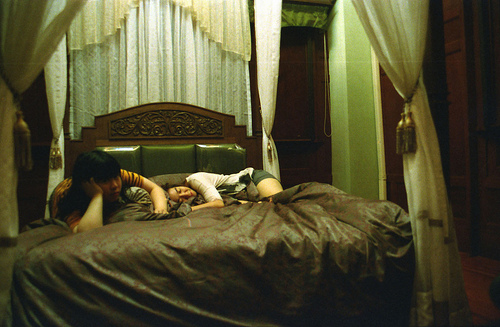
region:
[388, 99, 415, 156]
golden tassel on curtains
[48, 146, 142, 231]
woman with black hair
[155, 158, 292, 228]
woman laying on bed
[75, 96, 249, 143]
brown wooden bed headboard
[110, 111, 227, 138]
design on bed headboard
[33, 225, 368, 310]
brown bed comforter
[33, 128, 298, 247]
two women laying on bed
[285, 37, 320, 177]
large brown wooden door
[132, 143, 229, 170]
green cushions on bed headboard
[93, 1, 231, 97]
white curtains behind bed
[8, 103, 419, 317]
two people in a queen size bed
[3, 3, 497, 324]
a bed in a bedroom with people in it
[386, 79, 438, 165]
a tassel of a bedroom curtain to keep out mosquitoes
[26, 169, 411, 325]
a brown bed spread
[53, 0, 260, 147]
a white curtain covering window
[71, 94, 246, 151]
a wooden head board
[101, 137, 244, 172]
a group of pillows along head board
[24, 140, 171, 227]
a guy lying in bed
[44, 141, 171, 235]
a guy is laying with his head in his hand on a bed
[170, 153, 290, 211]
a woman is laying down with clothes on in bed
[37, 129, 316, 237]
people lying on a bed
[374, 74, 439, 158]
tassels on a bed curtain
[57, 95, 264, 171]
headboard of a bed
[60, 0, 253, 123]
curtains in a bedroom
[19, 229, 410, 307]
comforter on a bed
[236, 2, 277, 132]
wooden post of a bed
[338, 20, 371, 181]
green wall in a bedroom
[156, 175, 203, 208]
face of a sleeping woman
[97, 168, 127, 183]
eyes of an Asian woman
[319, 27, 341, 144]
rope to a shade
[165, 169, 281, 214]
The girl laying down.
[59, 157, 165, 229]
The girl leaning on her hand.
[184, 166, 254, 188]
The white shirt the girl is wearing.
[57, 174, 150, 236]
The orange and black shirt the girl is wearing.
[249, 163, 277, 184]
The shorts the girl is wearing.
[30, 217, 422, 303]
The brown blanket on the bed.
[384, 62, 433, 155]
The curtain tiers on the curtain on the right front of the bed.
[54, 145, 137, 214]
The girl's black hair that is leaning on her hand.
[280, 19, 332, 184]
The brown door near the top of the bed.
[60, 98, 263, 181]
The headboard of the bed the girls are laying on.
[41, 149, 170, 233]
young woman lying in a bed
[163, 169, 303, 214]
young woman lying in bed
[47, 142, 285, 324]
two young women lying in bed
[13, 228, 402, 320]
brown fabric on comforter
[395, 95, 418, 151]
golden fabric tassels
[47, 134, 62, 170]
golden fabric tassels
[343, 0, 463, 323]
sheer white drapes on a bedpost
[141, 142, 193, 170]
plastic covered pillow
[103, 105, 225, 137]
ornate wooden headboard design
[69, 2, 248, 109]
patterened white cloth